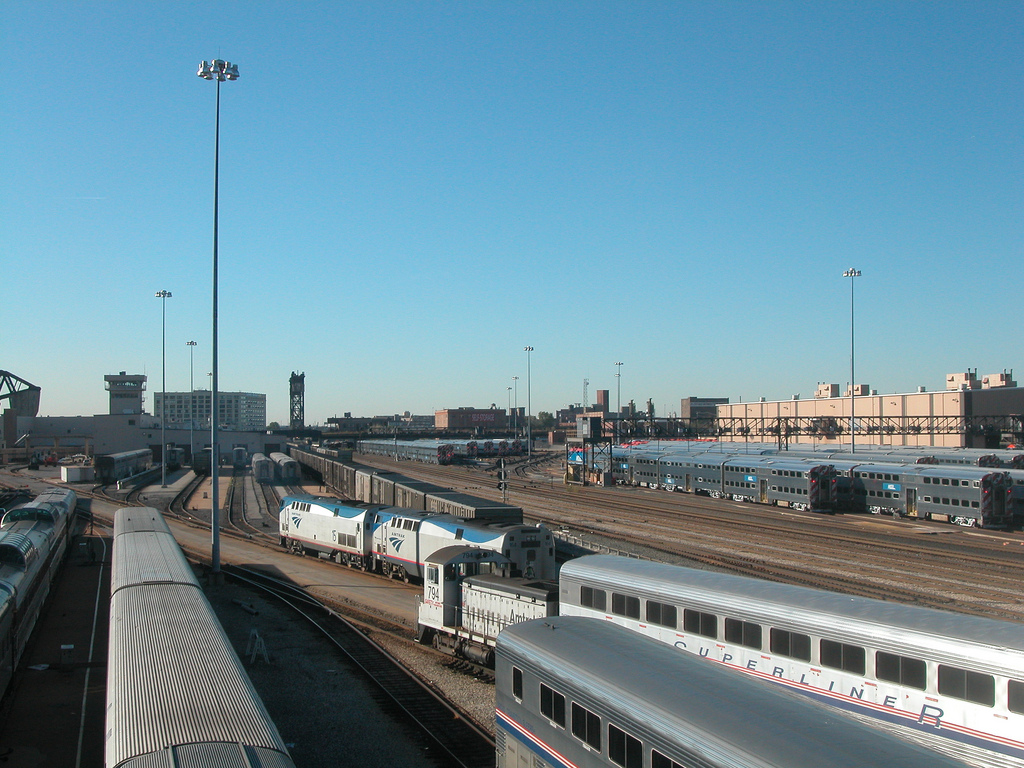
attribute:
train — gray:
[65, 487, 294, 753]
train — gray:
[503, 603, 871, 761]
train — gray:
[533, 541, 1022, 714]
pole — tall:
[194, 46, 231, 591]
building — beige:
[695, 381, 1018, 446]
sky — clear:
[186, 39, 966, 487]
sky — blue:
[250, 39, 991, 469]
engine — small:
[402, 541, 614, 691]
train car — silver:
[106, 586, 301, 764]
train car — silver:
[111, 528, 209, 585]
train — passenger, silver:
[96, 506, 311, 764]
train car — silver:
[115, 502, 178, 533]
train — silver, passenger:
[102, 498, 301, 764]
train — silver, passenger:
[627, 448, 837, 515]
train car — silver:
[627, 437, 677, 492]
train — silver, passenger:
[817, 459, 1018, 527]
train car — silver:
[852, 452, 911, 524]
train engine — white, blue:
[282, 493, 375, 563]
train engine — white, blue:
[368, 504, 550, 587]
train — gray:
[493, 616, 965, 764]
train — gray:
[562, 549, 1021, 763]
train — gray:
[552, 544, 1019, 740]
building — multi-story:
[152, 387, 267, 431]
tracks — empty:
[132, 465, 247, 507]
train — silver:
[559, 534, 1020, 755]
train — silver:
[488, 611, 994, 759]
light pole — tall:
[177, 50, 258, 563]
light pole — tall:
[134, 276, 178, 482]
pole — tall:
[182, 52, 256, 578]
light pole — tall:
[145, 276, 182, 495]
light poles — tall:
[145, 45, 264, 571]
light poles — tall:
[495, 251, 885, 459]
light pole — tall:
[827, 257, 877, 445]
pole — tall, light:
[832, 259, 869, 458]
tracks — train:
[115, 480, 481, 762]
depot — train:
[7, 436, 1016, 765]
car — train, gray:
[488, 603, 1018, 764]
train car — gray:
[912, 460, 1018, 534]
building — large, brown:
[719, 361, 1020, 444]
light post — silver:
[186, 49, 241, 596]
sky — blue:
[6, 8, 1016, 421]